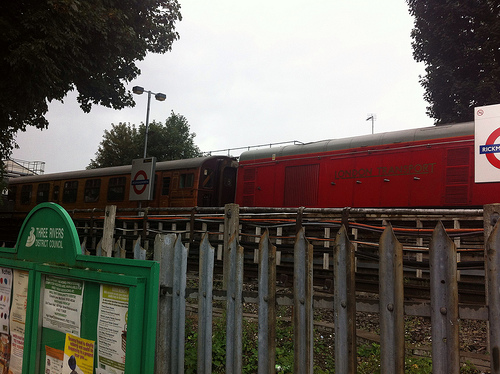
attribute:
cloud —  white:
[184, 108, 256, 150]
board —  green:
[0, 199, 159, 373]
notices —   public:
[36, 274, 85, 335]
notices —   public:
[93, 282, 133, 372]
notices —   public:
[65, 332, 97, 373]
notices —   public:
[45, 346, 64, 373]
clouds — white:
[256, 78, 362, 125]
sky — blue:
[9, 4, 479, 188]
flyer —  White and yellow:
[61, 329, 96, 371]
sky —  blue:
[280, 22, 367, 93]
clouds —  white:
[0, 1, 432, 173]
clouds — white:
[243, 13, 421, 108]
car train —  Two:
[235, 145, 480, 210]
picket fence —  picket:
[0, 207, 498, 369]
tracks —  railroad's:
[3, 234, 494, 362]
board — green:
[7, 201, 192, 372]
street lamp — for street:
[131, 82, 168, 157]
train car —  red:
[236, 120, 499, 284]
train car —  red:
[0, 153, 236, 265]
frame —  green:
[2, 198, 165, 368]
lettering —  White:
[22, 217, 61, 247]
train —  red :
[7, 122, 499, 224]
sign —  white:
[463, 102, 498, 189]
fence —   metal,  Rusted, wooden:
[94, 203, 476, 371]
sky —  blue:
[194, 12, 369, 94]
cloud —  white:
[151, 57, 239, 114]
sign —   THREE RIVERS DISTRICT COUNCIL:
[24, 225, 65, 250]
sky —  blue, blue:
[8, 0, 435, 172]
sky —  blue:
[213, 29, 360, 123]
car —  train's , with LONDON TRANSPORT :
[299, 113, 466, 197]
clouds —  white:
[281, 68, 353, 123]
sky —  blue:
[189, 7, 423, 134]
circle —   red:
[132, 167, 147, 196]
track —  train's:
[80, 250, 498, 264]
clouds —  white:
[365, 35, 415, 72]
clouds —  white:
[373, 90, 428, 129]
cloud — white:
[184, 6, 403, 102]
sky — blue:
[47, 111, 87, 157]